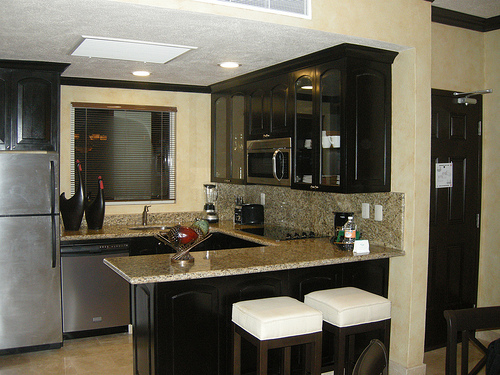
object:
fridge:
[0, 150, 65, 354]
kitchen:
[0, 0, 415, 374]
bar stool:
[231, 295, 324, 374]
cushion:
[230, 295, 325, 341]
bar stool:
[303, 286, 393, 374]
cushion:
[304, 286, 391, 329]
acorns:
[166, 224, 200, 246]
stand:
[156, 228, 213, 265]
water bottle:
[341, 215, 359, 251]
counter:
[103, 245, 406, 374]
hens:
[82, 175, 106, 229]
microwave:
[245, 136, 293, 186]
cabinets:
[207, 42, 400, 194]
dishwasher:
[60, 239, 132, 338]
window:
[71, 101, 177, 206]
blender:
[193, 183, 221, 226]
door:
[423, 88, 483, 353]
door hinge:
[477, 120, 482, 134]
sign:
[433, 160, 454, 189]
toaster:
[241, 203, 265, 226]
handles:
[49, 160, 59, 268]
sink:
[128, 226, 179, 232]